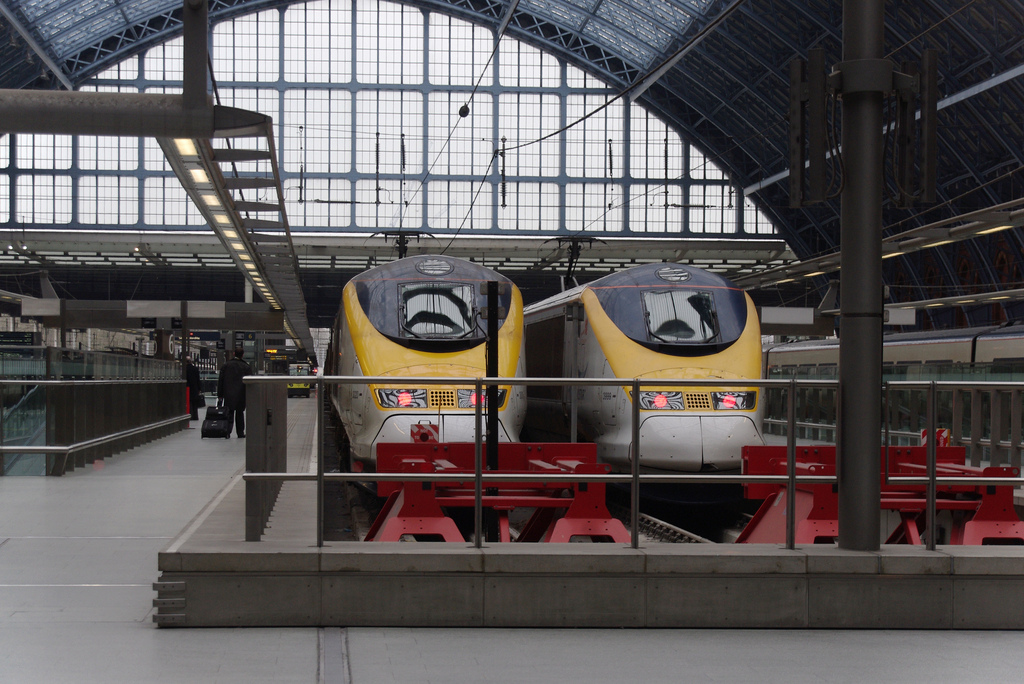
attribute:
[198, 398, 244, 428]
suitcase — black 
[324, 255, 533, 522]
train — pair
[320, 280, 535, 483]
train — yellow 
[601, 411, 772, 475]
bottom — white 